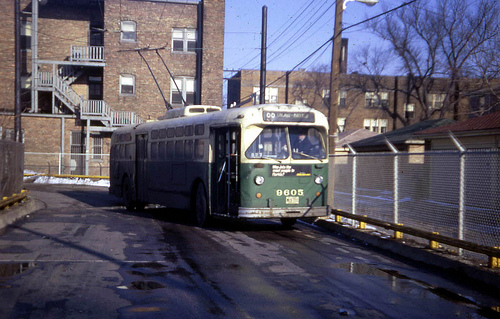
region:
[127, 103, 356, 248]
The front of the bus is green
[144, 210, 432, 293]
The street is wet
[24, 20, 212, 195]
Gray stairs are attached to the building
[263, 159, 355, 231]
White numbers are on the front of the bus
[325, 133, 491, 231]
A fence is next to the bus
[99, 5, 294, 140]
Windows are on the building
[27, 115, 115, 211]
A fence is in front of the building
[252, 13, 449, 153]
Power lines are on the pole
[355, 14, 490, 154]
Trees are in front of the building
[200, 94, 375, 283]
The bus is green and white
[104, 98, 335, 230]
green and white transit bus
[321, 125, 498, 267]
metal cyclone style fence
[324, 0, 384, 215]
street light with wood pole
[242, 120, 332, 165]
bus's windshield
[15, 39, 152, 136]
apartment outdoor staircase with metal railing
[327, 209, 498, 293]
small yellow barrier fence on curb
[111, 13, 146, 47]
window in brown colored brick building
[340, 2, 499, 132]
leafless tree in the city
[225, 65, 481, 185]
brick apartment building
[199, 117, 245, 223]
front door of bus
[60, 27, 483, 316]
a bus on the road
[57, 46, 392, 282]
a green bus on the raod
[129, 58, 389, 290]
a bus on the street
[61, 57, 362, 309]
a green bus on the street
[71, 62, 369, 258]
a passenger bus on the road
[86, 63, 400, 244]
a passenger bus on the street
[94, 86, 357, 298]
a green passenger bus on the road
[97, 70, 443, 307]
a green passenger bus on the street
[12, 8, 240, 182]
stairs on the side of a building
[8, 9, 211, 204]
a brick building with stairs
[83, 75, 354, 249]
the bus is moving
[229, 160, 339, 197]
the headlights are off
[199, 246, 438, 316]
the street is wet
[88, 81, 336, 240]
the bus is green and white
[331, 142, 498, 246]
the fence is grey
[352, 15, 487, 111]
the trees are bare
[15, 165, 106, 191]
snow on the side of the road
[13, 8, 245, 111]
building in the background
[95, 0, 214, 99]
the building is brown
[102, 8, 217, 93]
the building is made of bricks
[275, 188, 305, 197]
9605 numbers on front of bus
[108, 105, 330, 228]
green and white bus driving on road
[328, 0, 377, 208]
street light on brown wooden power line pole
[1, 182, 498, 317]
black and wet paved street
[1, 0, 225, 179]
brown brick building in background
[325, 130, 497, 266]
chain link fence next to road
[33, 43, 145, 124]
metal stairway for brick apartment building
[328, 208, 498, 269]
yellow guard rail on side of road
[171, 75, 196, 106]
window on front of large brick building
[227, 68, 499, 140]
large brick building in distance